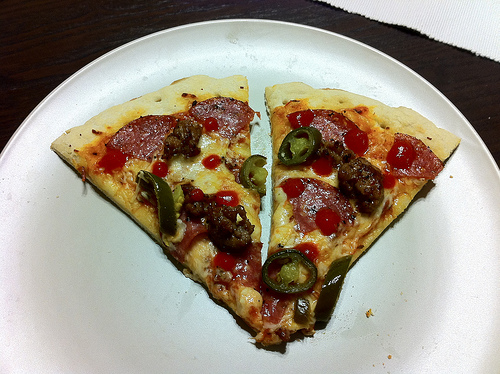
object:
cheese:
[195, 170, 230, 192]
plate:
[12, 16, 500, 371]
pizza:
[49, 68, 457, 345]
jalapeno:
[131, 173, 179, 235]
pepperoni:
[280, 178, 358, 236]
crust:
[64, 77, 245, 131]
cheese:
[188, 141, 227, 185]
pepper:
[278, 123, 321, 165]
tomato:
[286, 108, 370, 177]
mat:
[60, 23, 167, 105]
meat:
[161, 121, 203, 161]